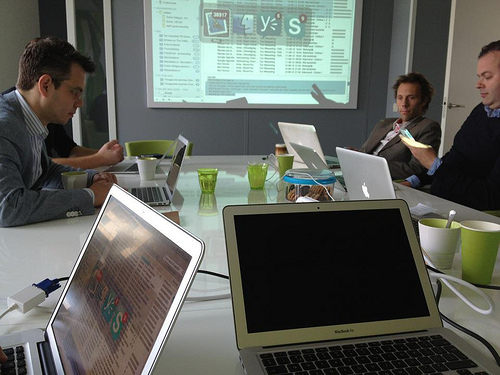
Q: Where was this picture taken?
A: Office.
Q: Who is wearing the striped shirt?
A: Left front man.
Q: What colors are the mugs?
A: Green and white.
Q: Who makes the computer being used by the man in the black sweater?
A: Apple.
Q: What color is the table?
A: White.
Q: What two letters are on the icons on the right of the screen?
A: Y and S.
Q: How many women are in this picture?
A: 0.